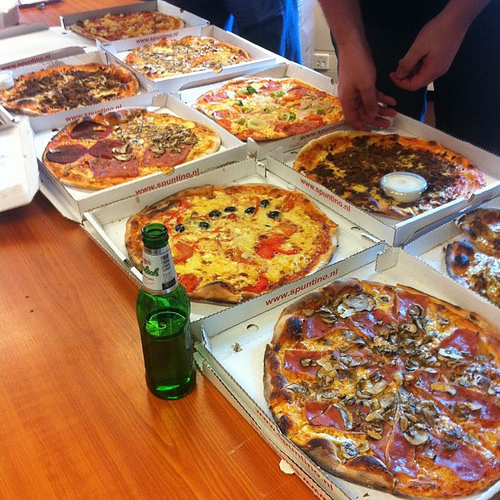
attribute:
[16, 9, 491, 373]
boxes — open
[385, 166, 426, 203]
container — white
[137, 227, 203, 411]
bottle — green, half full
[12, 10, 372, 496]
table — wooden, light brown, brown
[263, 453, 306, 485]
tap — white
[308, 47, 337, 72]
outlet — white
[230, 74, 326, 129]
bell pepper — few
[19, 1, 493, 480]
pizzas — different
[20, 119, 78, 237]
pizza box — white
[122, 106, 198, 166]
toppings — mushrooms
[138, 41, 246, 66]
cheese — white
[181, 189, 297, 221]
black olives — few